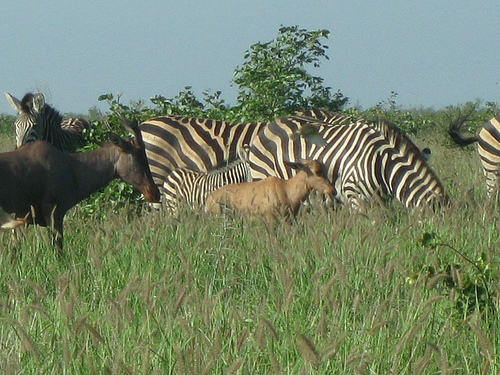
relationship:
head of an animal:
[103, 114, 164, 204] [3, 120, 160, 264]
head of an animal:
[103, 118, 164, 204] [442, 100, 499, 206]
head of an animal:
[103, 118, 164, 204] [6, 90, 105, 147]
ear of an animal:
[3, 91, 31, 114] [6, 90, 105, 147]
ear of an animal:
[31, 91, 45, 113] [6, 90, 105, 147]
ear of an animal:
[3, 91, 31, 114] [3, 120, 160, 264]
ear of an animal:
[3, 91, 31, 114] [442, 100, 499, 206]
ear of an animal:
[3, 91, 31, 114] [166, 148, 255, 217]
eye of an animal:
[135, 159, 145, 167] [3, 120, 160, 264]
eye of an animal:
[30, 123, 39, 131] [6, 90, 105, 147]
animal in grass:
[3, 120, 160, 264] [2, 137, 500, 374]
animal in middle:
[442, 100, 499, 206] [127, 1, 361, 373]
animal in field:
[442, 100, 499, 206] [2, 110, 498, 373]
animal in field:
[3, 120, 160, 264] [2, 110, 498, 373]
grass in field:
[2, 137, 500, 374] [2, 110, 498, 373]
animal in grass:
[442, 100, 499, 206] [2, 137, 500, 374]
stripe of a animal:
[150, 114, 214, 171] [442, 100, 499, 206]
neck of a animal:
[379, 144, 448, 205] [442, 100, 499, 206]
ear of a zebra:
[31, 91, 45, 113] [6, 90, 105, 147]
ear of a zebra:
[3, 91, 31, 114] [6, 90, 105, 147]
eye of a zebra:
[30, 123, 39, 131] [6, 90, 105, 147]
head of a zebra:
[103, 118, 164, 204] [6, 93, 95, 145]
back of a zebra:
[475, 111, 500, 227] [477, 113, 499, 218]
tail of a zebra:
[448, 107, 481, 148] [477, 113, 499, 218]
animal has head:
[442, 100, 499, 206] [103, 118, 164, 204]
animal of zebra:
[442, 100, 499, 206] [87, 78, 453, 333]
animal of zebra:
[442, 100, 499, 206] [187, 63, 472, 298]